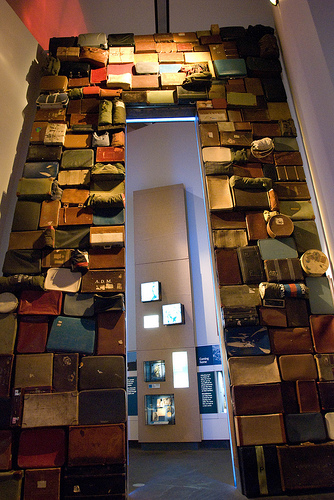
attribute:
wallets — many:
[217, 173, 299, 313]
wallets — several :
[97, 36, 231, 89]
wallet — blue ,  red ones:
[79, 49, 182, 70]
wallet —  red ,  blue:
[95, 58, 181, 80]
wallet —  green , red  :
[98, 60, 185, 78]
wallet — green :
[264, 251, 292, 282]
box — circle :
[300, 248, 323, 266]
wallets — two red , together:
[11, 307, 106, 399]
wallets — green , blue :
[5, 302, 111, 401]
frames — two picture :
[127, 172, 221, 495]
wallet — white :
[136, 276, 193, 337]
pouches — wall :
[13, 319, 121, 472]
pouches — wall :
[9, 344, 117, 461]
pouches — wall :
[16, 324, 111, 463]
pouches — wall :
[18, 317, 116, 452]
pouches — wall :
[12, 343, 115, 444]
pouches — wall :
[0, 292, 121, 395]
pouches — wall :
[35, 261, 101, 387]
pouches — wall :
[12, 263, 123, 465]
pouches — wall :
[33, 188, 108, 289]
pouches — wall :
[9, 265, 112, 450]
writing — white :
[5, 459, 261, 497]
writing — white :
[202, 278, 288, 441]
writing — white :
[158, 248, 253, 419]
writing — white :
[208, 323, 257, 454]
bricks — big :
[306, 83, 322, 107]